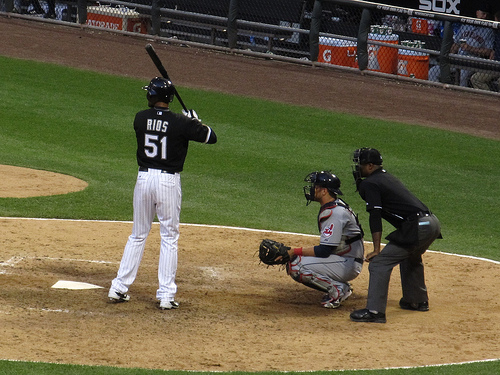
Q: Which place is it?
A: It is a field.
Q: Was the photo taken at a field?
A: Yes, it was taken in a field.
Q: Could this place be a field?
A: Yes, it is a field.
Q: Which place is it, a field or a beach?
A: It is a field.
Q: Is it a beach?
A: No, it is a field.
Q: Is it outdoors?
A: Yes, it is outdoors.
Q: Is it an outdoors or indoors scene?
A: It is outdoors.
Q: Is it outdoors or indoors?
A: It is outdoors.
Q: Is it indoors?
A: No, it is outdoors.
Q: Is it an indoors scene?
A: No, it is outdoors.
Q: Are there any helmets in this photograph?
A: Yes, there is a helmet.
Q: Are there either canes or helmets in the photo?
A: Yes, there is a helmet.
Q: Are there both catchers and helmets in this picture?
A: Yes, there are both a helmet and a catcher.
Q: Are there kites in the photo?
A: No, there are no kites.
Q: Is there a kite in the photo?
A: No, there are no kites.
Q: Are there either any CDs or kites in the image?
A: No, there are no kites or cds.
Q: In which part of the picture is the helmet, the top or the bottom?
A: The helmet is in the top of the image.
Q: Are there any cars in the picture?
A: No, there are no cars.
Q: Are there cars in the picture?
A: No, there are no cars.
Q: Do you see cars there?
A: No, there are no cars.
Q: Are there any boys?
A: No, there are no boys.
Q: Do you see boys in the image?
A: No, there are no boys.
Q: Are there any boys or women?
A: No, there are no boys or women.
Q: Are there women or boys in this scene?
A: No, there are no boys or women.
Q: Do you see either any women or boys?
A: No, there are no boys or women.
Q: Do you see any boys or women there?
A: No, there are no boys or women.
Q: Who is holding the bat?
A: The batter is holding the bat.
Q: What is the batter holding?
A: The batter is holding the bat.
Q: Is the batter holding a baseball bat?
A: No, the batter is holding the bat.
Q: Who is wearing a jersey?
A: The batter is wearing a jersey.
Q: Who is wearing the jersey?
A: The batter is wearing a jersey.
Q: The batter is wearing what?
A: The batter is wearing a jersey.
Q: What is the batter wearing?
A: The batter is wearing a jersey.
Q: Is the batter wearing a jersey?
A: Yes, the batter is wearing a jersey.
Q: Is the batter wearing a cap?
A: No, the batter is wearing a jersey.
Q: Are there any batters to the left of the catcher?
A: Yes, there is a batter to the left of the catcher.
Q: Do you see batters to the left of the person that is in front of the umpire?
A: Yes, there is a batter to the left of the catcher.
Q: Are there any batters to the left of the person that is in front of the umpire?
A: Yes, there is a batter to the left of the catcher.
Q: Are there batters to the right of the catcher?
A: No, the batter is to the left of the catcher.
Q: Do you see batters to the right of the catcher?
A: No, the batter is to the left of the catcher.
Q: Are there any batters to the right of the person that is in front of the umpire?
A: No, the batter is to the left of the catcher.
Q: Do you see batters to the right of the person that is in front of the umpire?
A: No, the batter is to the left of the catcher.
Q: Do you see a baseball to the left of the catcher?
A: No, there is a batter to the left of the catcher.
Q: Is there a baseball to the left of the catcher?
A: No, there is a batter to the left of the catcher.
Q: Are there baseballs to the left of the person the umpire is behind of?
A: No, there is a batter to the left of the catcher.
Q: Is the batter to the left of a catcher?
A: Yes, the batter is to the left of a catcher.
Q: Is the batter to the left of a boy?
A: No, the batter is to the left of a catcher.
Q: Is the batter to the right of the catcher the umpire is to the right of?
A: No, the batter is to the left of the catcher.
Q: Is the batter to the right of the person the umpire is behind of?
A: No, the batter is to the left of the catcher.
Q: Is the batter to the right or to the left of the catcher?
A: The batter is to the left of the catcher.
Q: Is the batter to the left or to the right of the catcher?
A: The batter is to the left of the catcher.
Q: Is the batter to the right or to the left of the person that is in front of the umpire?
A: The batter is to the left of the catcher.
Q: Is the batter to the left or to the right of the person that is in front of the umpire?
A: The batter is to the left of the catcher.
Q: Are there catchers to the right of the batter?
A: Yes, there is a catcher to the right of the batter.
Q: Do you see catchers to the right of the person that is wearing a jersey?
A: Yes, there is a catcher to the right of the batter.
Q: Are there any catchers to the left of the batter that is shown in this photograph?
A: No, the catcher is to the right of the batter.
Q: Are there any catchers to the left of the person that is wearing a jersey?
A: No, the catcher is to the right of the batter.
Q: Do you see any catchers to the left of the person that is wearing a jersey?
A: No, the catcher is to the right of the batter.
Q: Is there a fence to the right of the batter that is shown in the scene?
A: No, there is a catcher to the right of the batter.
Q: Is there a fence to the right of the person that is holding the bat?
A: No, there is a catcher to the right of the batter.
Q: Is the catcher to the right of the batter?
A: Yes, the catcher is to the right of the batter.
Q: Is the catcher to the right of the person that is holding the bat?
A: Yes, the catcher is to the right of the batter.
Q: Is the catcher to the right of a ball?
A: No, the catcher is to the right of the batter.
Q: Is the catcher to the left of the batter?
A: No, the catcher is to the right of the batter.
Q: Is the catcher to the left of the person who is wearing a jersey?
A: No, the catcher is to the right of the batter.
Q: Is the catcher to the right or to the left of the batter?
A: The catcher is to the right of the batter.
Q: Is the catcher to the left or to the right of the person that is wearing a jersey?
A: The catcher is to the right of the batter.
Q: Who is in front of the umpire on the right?
A: The catcher is in front of the umpire.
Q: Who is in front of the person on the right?
A: The catcher is in front of the umpire.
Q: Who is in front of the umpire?
A: The catcher is in front of the umpire.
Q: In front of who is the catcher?
A: The catcher is in front of the umpire.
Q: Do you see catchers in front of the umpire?
A: Yes, there is a catcher in front of the umpire.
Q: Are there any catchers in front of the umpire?
A: Yes, there is a catcher in front of the umpire.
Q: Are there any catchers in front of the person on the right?
A: Yes, there is a catcher in front of the umpire.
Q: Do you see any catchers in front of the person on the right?
A: Yes, there is a catcher in front of the umpire.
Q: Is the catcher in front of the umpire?
A: Yes, the catcher is in front of the umpire.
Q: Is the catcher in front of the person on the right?
A: Yes, the catcher is in front of the umpire.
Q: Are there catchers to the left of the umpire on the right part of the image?
A: Yes, there is a catcher to the left of the umpire.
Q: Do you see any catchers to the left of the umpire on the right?
A: Yes, there is a catcher to the left of the umpire.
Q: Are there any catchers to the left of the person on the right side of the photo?
A: Yes, there is a catcher to the left of the umpire.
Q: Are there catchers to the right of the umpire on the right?
A: No, the catcher is to the left of the umpire.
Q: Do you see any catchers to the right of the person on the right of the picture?
A: No, the catcher is to the left of the umpire.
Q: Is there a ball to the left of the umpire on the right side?
A: No, there is a catcher to the left of the umpire.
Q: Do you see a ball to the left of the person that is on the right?
A: No, there is a catcher to the left of the umpire.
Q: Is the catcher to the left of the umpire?
A: Yes, the catcher is to the left of the umpire.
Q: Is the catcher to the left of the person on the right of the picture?
A: Yes, the catcher is to the left of the umpire.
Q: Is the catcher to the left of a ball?
A: No, the catcher is to the left of the umpire.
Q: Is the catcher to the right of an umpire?
A: No, the catcher is to the left of an umpire.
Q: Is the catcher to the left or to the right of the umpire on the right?
A: The catcher is to the left of the umpire.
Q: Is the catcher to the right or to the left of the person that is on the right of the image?
A: The catcher is to the left of the umpire.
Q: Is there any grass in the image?
A: Yes, there is grass.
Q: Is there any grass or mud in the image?
A: Yes, there is grass.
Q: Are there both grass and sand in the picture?
A: No, there is grass but no sand.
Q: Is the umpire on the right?
A: Yes, the umpire is on the right of the image.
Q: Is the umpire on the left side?
A: No, the umpire is on the right of the image.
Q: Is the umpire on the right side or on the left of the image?
A: The umpire is on the right of the image.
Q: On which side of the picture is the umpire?
A: The umpire is on the right of the image.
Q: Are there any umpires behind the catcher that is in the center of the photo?
A: Yes, there is an umpire behind the catcher.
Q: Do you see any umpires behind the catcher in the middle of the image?
A: Yes, there is an umpire behind the catcher.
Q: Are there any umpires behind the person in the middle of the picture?
A: Yes, there is an umpire behind the catcher.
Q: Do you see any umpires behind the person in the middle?
A: Yes, there is an umpire behind the catcher.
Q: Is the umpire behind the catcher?
A: Yes, the umpire is behind the catcher.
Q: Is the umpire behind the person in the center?
A: Yes, the umpire is behind the catcher.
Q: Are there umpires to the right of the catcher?
A: Yes, there is an umpire to the right of the catcher.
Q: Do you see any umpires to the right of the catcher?
A: Yes, there is an umpire to the right of the catcher.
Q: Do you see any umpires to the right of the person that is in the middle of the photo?
A: Yes, there is an umpire to the right of the catcher.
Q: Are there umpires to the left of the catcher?
A: No, the umpire is to the right of the catcher.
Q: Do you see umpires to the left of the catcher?
A: No, the umpire is to the right of the catcher.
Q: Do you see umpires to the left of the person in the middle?
A: No, the umpire is to the right of the catcher.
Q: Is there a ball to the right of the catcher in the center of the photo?
A: No, there is an umpire to the right of the catcher.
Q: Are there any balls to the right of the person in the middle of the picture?
A: No, there is an umpire to the right of the catcher.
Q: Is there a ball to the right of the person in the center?
A: No, there is an umpire to the right of the catcher.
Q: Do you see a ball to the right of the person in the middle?
A: No, there is an umpire to the right of the catcher.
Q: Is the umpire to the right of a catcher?
A: Yes, the umpire is to the right of a catcher.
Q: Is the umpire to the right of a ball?
A: No, the umpire is to the right of a catcher.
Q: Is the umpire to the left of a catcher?
A: No, the umpire is to the right of a catcher.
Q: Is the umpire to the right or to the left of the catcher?
A: The umpire is to the right of the catcher.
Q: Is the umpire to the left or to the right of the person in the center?
A: The umpire is to the right of the catcher.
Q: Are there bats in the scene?
A: Yes, there is a bat.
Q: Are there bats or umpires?
A: Yes, there is a bat.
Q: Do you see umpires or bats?
A: Yes, there is a bat.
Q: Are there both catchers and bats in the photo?
A: Yes, there are both a bat and a catcher.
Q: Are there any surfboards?
A: No, there are no surfboards.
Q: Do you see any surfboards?
A: No, there are no surfboards.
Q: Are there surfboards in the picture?
A: No, there are no surfboards.